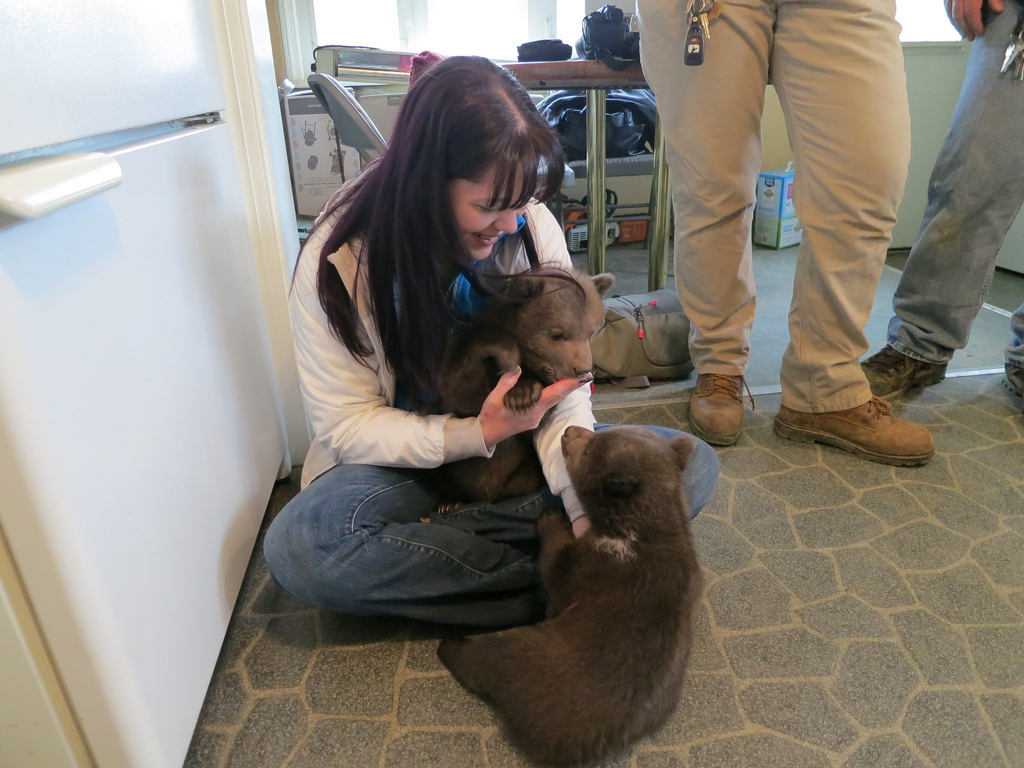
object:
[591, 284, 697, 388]
brown bag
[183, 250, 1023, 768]
ground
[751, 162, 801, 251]
box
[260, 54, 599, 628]
lady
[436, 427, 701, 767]
bear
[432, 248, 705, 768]
both bears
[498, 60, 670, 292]
small table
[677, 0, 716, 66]
car keys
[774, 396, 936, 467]
brown boots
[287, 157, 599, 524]
sweater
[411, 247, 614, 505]
bear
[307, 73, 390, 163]
back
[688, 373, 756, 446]
boot